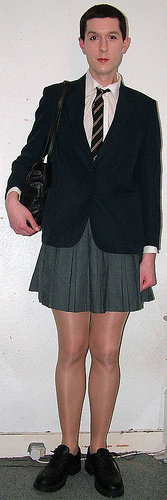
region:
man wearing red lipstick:
[96, 56, 110, 63]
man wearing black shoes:
[38, 453, 124, 493]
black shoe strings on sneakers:
[49, 449, 61, 468]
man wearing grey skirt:
[55, 268, 97, 316]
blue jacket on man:
[123, 130, 135, 153]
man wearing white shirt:
[109, 94, 114, 108]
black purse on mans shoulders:
[25, 167, 46, 200]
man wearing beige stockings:
[98, 326, 111, 356]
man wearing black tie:
[96, 92, 101, 123]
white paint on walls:
[14, 402, 33, 414]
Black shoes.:
[30, 440, 126, 498]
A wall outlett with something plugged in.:
[28, 441, 48, 459]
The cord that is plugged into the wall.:
[31, 450, 165, 463]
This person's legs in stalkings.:
[46, 299, 137, 458]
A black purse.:
[18, 79, 73, 232]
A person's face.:
[78, 3, 129, 82]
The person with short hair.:
[9, 0, 160, 497]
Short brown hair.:
[74, 1, 127, 41]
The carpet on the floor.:
[1, 450, 166, 499]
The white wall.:
[0, 0, 166, 430]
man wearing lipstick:
[56, 11, 142, 83]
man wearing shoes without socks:
[19, 429, 145, 498]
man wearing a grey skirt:
[19, 203, 164, 329]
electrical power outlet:
[22, 419, 147, 471]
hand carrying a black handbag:
[12, 132, 89, 239]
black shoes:
[78, 432, 140, 483]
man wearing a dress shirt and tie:
[58, 47, 147, 171]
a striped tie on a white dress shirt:
[78, 67, 131, 155]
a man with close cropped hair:
[75, 1, 139, 98]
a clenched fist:
[123, 231, 163, 295]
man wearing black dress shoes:
[13, 3, 161, 489]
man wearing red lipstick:
[15, 1, 150, 487]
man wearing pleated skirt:
[20, 3, 155, 489]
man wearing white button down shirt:
[18, 6, 154, 489]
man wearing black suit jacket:
[5, 6, 154, 474]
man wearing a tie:
[4, 5, 158, 490]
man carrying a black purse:
[12, 4, 159, 493]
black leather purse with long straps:
[15, 73, 67, 233]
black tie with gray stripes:
[85, 87, 109, 176]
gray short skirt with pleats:
[34, 213, 157, 315]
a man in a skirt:
[17, 4, 162, 348]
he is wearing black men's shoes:
[46, 443, 133, 497]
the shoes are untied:
[42, 444, 129, 499]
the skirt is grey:
[23, 218, 166, 334]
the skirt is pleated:
[28, 220, 151, 330]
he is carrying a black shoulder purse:
[3, 67, 76, 235]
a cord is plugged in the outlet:
[26, 443, 140, 466]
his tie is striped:
[85, 85, 106, 154]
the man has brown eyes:
[65, 0, 138, 83]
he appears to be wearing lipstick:
[81, 4, 144, 73]